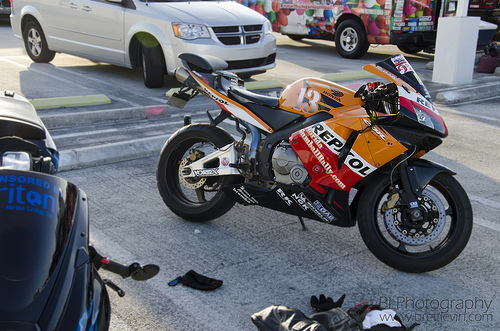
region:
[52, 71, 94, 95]
white line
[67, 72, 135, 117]
white line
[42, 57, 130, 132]
white line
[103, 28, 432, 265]
the bike is orange and black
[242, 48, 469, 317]
the bike is orange and black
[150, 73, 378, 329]
the bike is orange and black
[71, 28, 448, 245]
motorcycle in front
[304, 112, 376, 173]
logo on side of cycle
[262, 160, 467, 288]
front black wheel of cycle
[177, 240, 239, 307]
black object on ground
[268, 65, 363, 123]
orange paint on front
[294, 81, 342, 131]
number printed on side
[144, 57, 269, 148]
back end of cycle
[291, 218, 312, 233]
small black kickstand of cycle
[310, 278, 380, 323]
cycle gear on ground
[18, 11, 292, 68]
silver car parked in space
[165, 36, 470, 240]
motorcycle is orange red and black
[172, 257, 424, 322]
clothing on the ground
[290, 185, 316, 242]
the kick stand is down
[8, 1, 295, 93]
the car is white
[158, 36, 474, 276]
the motorcycle is parked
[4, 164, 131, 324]
the object is black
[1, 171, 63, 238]
blue lettering on object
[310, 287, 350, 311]
the glove is black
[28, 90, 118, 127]
yellow road bump on ground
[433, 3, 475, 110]
white object next to vehicles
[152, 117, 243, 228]
black tire on a motorcycle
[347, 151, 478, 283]
black tire on a motorcycle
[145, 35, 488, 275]
orange and black motorcycle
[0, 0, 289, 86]
white van parked on the street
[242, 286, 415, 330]
motorcycle clothes lying on the ground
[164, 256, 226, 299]
black glove on the ground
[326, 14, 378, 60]
black tire and rim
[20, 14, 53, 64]
black tire and rim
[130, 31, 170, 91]
black tire and rim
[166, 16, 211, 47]
headlight on a car